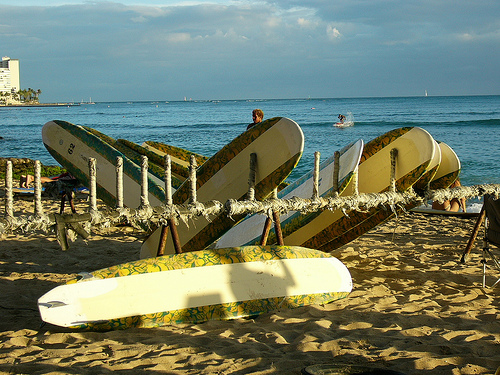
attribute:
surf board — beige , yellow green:
[32, 241, 356, 333]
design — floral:
[66, 242, 331, 285]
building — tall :
[2, 31, 49, 130]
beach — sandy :
[12, 168, 498, 374]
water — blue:
[0, 97, 499, 184]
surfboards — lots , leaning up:
[33, 112, 478, 247]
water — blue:
[109, 76, 473, 186]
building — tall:
[0, 54, 20, 104]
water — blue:
[123, 111, 193, 133]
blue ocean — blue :
[13, 87, 499, 210]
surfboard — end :
[5, 211, 380, 368]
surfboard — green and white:
[141, 116, 303, 255]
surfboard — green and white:
[274, 124, 431, 248]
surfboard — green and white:
[322, 131, 439, 251]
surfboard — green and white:
[431, 138, 460, 193]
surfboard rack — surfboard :
[20, 149, 215, 233]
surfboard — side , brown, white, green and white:
[34, 245, 352, 325]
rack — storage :
[0, 148, 499, 244]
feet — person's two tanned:
[54, 205, 96, 225]